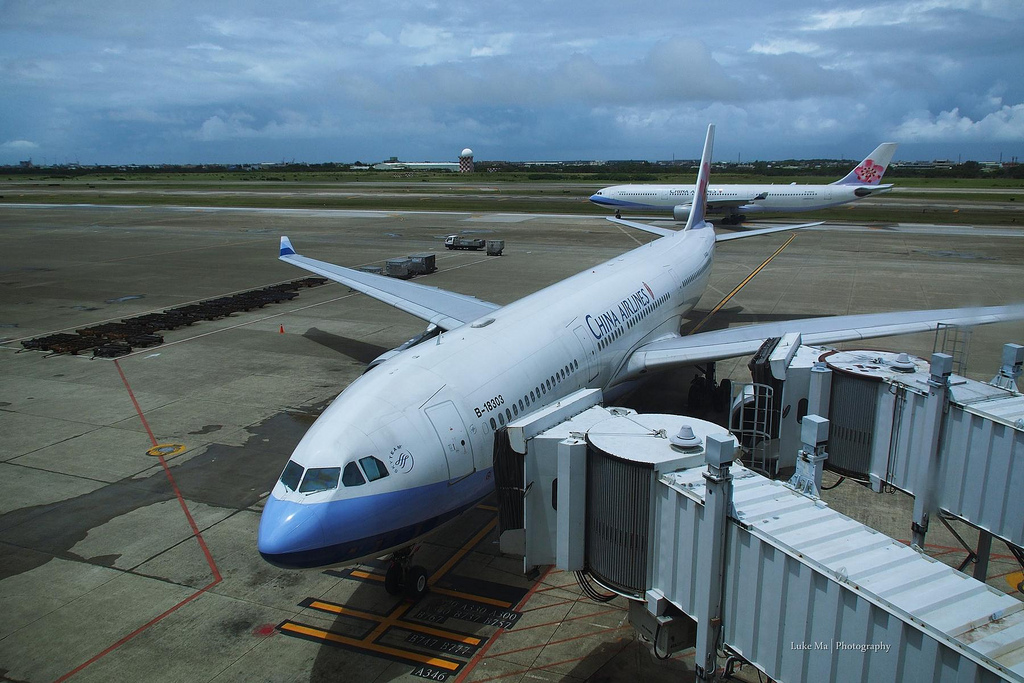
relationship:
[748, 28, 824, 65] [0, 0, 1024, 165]
cloud in blue sky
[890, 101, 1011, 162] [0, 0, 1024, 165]
cloud in blue sky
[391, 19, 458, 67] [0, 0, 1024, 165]
cloud in blue sky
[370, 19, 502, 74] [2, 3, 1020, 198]
cloud in sky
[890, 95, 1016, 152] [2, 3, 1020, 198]
cloud in sky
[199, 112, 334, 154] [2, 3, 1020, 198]
cloud in sky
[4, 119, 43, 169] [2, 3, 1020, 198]
cloud in sky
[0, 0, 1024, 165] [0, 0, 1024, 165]
blue sky in blue sky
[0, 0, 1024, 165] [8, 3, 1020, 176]
blue sky in sky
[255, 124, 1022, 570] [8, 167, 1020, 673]
airplane on ground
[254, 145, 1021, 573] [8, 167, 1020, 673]
airplane on ground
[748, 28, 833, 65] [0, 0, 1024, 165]
cloud in blue sky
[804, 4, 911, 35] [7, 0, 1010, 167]
white cloud in blue sky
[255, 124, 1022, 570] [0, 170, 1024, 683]
airplane at ground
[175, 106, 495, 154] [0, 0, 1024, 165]
clouds in blue sky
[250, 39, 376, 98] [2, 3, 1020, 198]
clouds in sky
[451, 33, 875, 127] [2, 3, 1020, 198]
clodus in sky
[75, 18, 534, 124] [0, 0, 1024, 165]
cloud in blue sky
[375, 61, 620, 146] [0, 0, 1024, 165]
cloud in blue sky